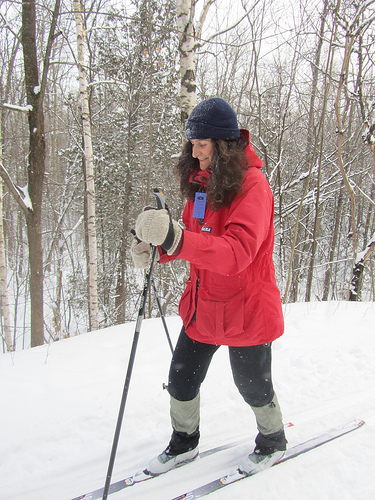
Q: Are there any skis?
A: Yes, there are skis.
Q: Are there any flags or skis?
A: Yes, there are skis.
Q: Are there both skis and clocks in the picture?
A: No, there are skis but no clocks.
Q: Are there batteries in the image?
A: No, there are no batteries.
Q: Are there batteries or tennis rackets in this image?
A: No, there are no batteries or tennis rackets.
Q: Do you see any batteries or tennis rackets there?
A: No, there are no batteries or tennis rackets.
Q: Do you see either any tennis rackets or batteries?
A: No, there are no batteries or tennis rackets.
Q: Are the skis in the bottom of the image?
A: Yes, the skis are in the bottom of the image.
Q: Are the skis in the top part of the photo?
A: No, the skis are in the bottom of the image.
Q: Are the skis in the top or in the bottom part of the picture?
A: The skis are in the bottom of the image.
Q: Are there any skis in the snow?
A: Yes, there are skis in the snow.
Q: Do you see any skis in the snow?
A: Yes, there are skis in the snow.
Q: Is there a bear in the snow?
A: No, there are skis in the snow.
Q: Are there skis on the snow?
A: Yes, there are skis on the snow.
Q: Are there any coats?
A: Yes, there is a coat.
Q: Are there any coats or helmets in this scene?
A: Yes, there is a coat.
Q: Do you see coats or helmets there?
A: Yes, there is a coat.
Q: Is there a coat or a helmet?
A: Yes, there is a coat.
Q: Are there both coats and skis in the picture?
A: Yes, there are both a coat and skis.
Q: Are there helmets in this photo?
A: No, there are no helmets.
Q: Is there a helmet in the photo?
A: No, there are no helmets.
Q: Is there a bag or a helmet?
A: No, there are no helmets or bags.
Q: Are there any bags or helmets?
A: No, there are no helmets or bags.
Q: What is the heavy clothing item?
A: The clothing item is a coat.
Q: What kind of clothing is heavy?
A: The clothing is a coat.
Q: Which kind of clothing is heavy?
A: The clothing is a coat.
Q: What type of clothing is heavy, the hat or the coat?
A: The coat is heavy.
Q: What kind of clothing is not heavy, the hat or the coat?
A: The hat is not heavy.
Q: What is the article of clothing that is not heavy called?
A: The clothing item is a hat.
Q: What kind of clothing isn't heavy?
A: The clothing is a hat.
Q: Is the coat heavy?
A: Yes, the coat is heavy.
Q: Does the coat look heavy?
A: Yes, the coat is heavy.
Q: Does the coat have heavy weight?
A: Yes, the coat is heavy.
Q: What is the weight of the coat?
A: The coat is heavy.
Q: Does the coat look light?
A: No, the coat is heavy.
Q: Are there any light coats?
A: No, there is a coat but it is heavy.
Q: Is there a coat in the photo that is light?
A: No, there is a coat but it is heavy.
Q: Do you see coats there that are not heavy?
A: No, there is a coat but it is heavy.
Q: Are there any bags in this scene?
A: No, there are no bags.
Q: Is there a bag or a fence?
A: No, there are no bags or fences.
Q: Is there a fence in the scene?
A: No, there are no fences.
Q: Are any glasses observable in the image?
A: No, there are no glasses.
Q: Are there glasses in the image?
A: No, there are no glasses.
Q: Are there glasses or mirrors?
A: No, there are no glasses or mirrors.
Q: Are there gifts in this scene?
A: No, there are no gifts.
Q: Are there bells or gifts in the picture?
A: No, there are no gifts or bells.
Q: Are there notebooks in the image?
A: No, there are no notebooks.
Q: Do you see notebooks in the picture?
A: No, there are no notebooks.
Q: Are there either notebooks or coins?
A: No, there are no notebooks or coins.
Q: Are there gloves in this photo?
A: Yes, there are gloves.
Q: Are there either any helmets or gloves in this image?
A: Yes, there are gloves.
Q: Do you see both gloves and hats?
A: Yes, there are both gloves and a hat.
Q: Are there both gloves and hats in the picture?
A: Yes, there are both gloves and a hat.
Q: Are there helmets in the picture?
A: No, there are no helmets.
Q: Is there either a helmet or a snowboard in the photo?
A: No, there are no helmets or snowboards.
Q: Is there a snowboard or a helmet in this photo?
A: No, there are no helmets or snowboards.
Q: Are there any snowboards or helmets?
A: No, there are no helmets or snowboards.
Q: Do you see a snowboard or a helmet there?
A: No, there are no helmets or snowboards.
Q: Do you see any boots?
A: Yes, there are boots.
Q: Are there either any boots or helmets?
A: Yes, there are boots.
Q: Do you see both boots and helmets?
A: No, there are boots but no helmets.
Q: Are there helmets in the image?
A: No, there are no helmets.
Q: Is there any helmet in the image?
A: No, there are no helmets.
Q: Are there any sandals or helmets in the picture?
A: No, there are no helmets or sandals.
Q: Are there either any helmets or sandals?
A: No, there are no helmets or sandals.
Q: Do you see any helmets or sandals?
A: No, there are no helmets or sandals.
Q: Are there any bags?
A: No, there are no bags.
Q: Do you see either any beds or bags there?
A: No, there are no bags or beds.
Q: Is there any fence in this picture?
A: No, there are no fences.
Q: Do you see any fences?
A: No, there are no fences.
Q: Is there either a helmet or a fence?
A: No, there are no fences or helmets.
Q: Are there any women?
A: Yes, there is a woman.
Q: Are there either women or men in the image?
A: Yes, there is a woman.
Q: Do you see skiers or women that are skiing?
A: Yes, the woman is skiing.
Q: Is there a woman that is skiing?
A: Yes, there is a woman that is skiing.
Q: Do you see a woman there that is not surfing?
A: Yes, there is a woman that is skiing .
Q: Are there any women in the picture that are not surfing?
A: Yes, there is a woman that is skiing.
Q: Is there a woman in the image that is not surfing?
A: Yes, there is a woman that is skiing.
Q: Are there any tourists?
A: No, there are no tourists.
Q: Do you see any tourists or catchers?
A: No, there are no tourists or catchers.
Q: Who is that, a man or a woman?
A: That is a woman.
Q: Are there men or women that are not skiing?
A: No, there is a woman but she is skiing.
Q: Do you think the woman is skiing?
A: Yes, the woman is skiing.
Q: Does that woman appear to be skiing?
A: Yes, the woman is skiing.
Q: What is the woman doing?
A: The woman is skiing.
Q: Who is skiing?
A: The woman is skiing.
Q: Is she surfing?
A: No, the woman is skiing.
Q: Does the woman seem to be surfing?
A: No, the woman is skiing.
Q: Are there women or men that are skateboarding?
A: No, there is a woman but she is skiing.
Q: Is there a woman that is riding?
A: No, there is a woman but she is skiing.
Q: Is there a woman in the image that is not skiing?
A: No, there is a woman but she is skiing.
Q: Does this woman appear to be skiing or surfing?
A: The woman is skiing.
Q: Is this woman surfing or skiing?
A: The woman is skiing.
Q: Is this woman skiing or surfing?
A: The woman is skiing.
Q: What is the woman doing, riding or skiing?
A: The woman is skiing.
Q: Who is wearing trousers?
A: The woman is wearing trousers.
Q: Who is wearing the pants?
A: The woman is wearing trousers.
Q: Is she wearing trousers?
A: Yes, the woman is wearing trousers.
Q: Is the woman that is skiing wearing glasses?
A: No, the woman is wearing trousers.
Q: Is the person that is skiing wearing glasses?
A: No, the woman is wearing trousers.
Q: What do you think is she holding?
A: The woman is holding the pole.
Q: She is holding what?
A: The woman is holding the pole.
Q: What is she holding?
A: The woman is holding the pole.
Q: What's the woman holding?
A: The woman is holding the pole.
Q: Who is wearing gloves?
A: The woman is wearing gloves.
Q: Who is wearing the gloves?
A: The woman is wearing gloves.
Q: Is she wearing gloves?
A: Yes, the woman is wearing gloves.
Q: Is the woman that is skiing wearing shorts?
A: No, the woman is wearing gloves.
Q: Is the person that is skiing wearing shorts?
A: No, the woman is wearing gloves.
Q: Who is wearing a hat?
A: The woman is wearing a hat.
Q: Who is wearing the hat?
A: The woman is wearing a hat.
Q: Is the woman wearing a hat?
A: Yes, the woman is wearing a hat.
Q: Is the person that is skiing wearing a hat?
A: Yes, the woman is wearing a hat.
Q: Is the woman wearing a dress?
A: No, the woman is wearing a hat.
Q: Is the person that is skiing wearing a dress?
A: No, the woman is wearing a hat.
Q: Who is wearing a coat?
A: The woman is wearing a coat.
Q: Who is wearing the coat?
A: The woman is wearing a coat.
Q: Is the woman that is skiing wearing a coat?
A: Yes, the woman is wearing a coat.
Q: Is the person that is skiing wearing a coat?
A: Yes, the woman is wearing a coat.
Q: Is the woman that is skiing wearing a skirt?
A: No, the woman is wearing a coat.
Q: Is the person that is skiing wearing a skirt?
A: No, the woman is wearing a coat.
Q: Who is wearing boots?
A: The woman is wearing boots.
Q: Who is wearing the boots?
A: The woman is wearing boots.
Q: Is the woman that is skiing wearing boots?
A: Yes, the woman is wearing boots.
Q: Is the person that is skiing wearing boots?
A: Yes, the woman is wearing boots.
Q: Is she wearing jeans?
A: No, the woman is wearing boots.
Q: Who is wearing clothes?
A: The woman is wearing clothes.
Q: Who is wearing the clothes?
A: The woman is wearing clothes.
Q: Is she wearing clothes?
A: Yes, the woman is wearing clothes.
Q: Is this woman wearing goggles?
A: No, the woman is wearing clothes.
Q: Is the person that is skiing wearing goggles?
A: No, the woman is wearing clothes.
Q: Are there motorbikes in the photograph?
A: No, there are no motorbikes.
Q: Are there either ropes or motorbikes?
A: No, there are no motorbikes or ropes.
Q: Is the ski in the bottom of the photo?
A: Yes, the ski is in the bottom of the image.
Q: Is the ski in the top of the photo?
A: No, the ski is in the bottom of the image.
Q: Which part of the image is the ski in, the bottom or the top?
A: The ski is in the bottom of the image.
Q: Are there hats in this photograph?
A: Yes, there is a hat.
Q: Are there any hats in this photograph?
A: Yes, there is a hat.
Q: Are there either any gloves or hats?
A: Yes, there is a hat.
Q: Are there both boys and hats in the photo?
A: No, there is a hat but no boys.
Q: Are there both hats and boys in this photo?
A: No, there is a hat but no boys.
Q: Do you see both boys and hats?
A: No, there is a hat but no boys.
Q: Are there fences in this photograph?
A: No, there are no fences.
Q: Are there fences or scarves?
A: No, there are no fences or scarves.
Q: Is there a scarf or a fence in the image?
A: No, there are no fences or scarves.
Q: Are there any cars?
A: No, there are no cars.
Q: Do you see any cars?
A: No, there are no cars.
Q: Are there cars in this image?
A: No, there are no cars.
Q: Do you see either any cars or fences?
A: No, there are no cars or fences.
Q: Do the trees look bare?
A: Yes, the trees are bare.